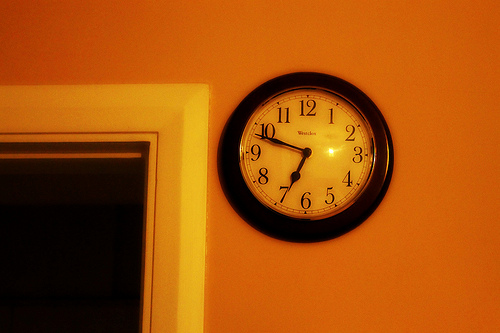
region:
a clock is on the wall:
[215, 70, 393, 241]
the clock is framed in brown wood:
[216, 66, 393, 241]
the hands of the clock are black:
[250, 126, 311, 201]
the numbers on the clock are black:
[242, 92, 370, 217]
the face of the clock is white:
[240, 85, 367, 210]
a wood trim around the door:
[3, 80, 203, 330]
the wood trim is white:
[0, 85, 205, 331]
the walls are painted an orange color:
[6, 10, 496, 326]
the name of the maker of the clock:
[292, 125, 318, 140]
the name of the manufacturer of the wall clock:
[293, 127, 321, 137]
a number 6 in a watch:
[299, 187, 314, 211]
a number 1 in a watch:
[257, 120, 262, 140]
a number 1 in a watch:
[272, 100, 280, 122]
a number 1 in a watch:
[281, 100, 291, 120]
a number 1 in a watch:
[297, 93, 304, 114]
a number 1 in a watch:
[323, 101, 336, 123]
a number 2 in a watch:
[305, 95, 316, 115]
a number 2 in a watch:
[340, 120, 355, 140]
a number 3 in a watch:
[350, 145, 362, 160]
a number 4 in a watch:
[338, 162, 355, 189]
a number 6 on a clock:
[298, 185, 315, 211]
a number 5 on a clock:
[323, 182, 341, 213]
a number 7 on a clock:
[274, 182, 289, 203]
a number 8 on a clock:
[255, 165, 273, 187]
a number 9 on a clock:
[246, 143, 263, 163]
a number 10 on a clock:
[258, 120, 275, 142]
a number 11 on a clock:
[273, 101, 295, 125]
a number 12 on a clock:
[298, 96, 318, 119]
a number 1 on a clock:
[324, 104, 337, 128]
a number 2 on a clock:
[343, 118, 358, 145]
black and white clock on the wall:
[216, 65, 394, 245]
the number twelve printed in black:
[298, 98, 315, 120]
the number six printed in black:
[299, 190, 314, 208]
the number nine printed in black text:
[249, 140, 262, 165]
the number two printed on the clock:
[341, 123, 356, 144]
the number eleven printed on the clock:
[276, 105, 295, 125]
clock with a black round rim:
[215, 64, 397, 245]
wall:
[398, 50, 499, 330]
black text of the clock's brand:
[294, 128, 319, 137]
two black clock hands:
[255, 131, 318, 190]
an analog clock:
[209, 63, 411, 253]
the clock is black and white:
[191, 48, 397, 245]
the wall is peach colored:
[200, 17, 498, 324]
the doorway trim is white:
[7, 53, 224, 331]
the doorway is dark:
[2, 78, 217, 331]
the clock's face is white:
[218, 50, 410, 251]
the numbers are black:
[217, 53, 401, 242]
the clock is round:
[196, 51, 402, 251]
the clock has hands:
[215, 56, 407, 253]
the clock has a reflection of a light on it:
[311, 133, 346, 173]